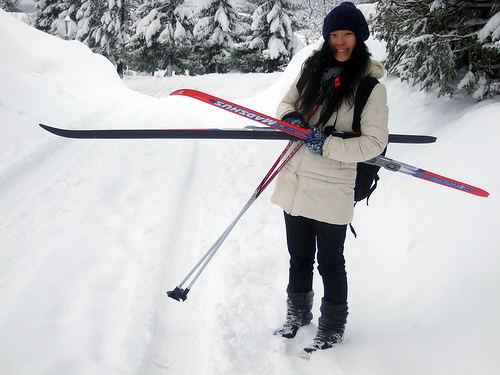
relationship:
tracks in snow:
[4, 88, 209, 372] [0, 3, 497, 371]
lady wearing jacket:
[265, 1, 392, 371] [269, 50, 390, 226]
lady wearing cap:
[265, 1, 392, 371] [299, 5, 410, 63]